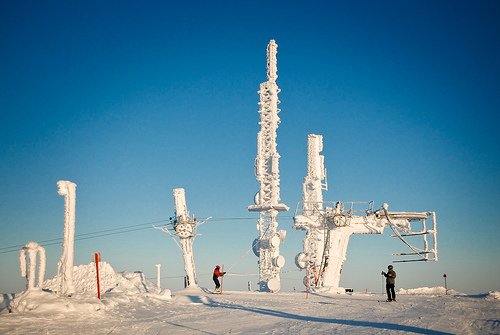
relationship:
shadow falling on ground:
[0, 313, 500, 335] [2, 290, 498, 333]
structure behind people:
[165, 188, 202, 288] [212, 265, 226, 292]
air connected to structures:
[6, 4, 490, 300] [218, 38, 408, 292]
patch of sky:
[20, 20, 239, 180] [0, 5, 495, 290]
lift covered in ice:
[350, 196, 448, 272] [309, 209, 409, 234]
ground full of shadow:
[2, 290, 498, 333] [0, 313, 500, 335]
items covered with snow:
[16, 43, 447, 298] [14, 40, 446, 299]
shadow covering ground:
[0, 313, 500, 335] [0, 284, 500, 332]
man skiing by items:
[381, 265, 396, 302] [234, 36, 449, 296]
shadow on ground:
[197, 295, 447, 333] [19, 286, 497, 333]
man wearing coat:
[381, 265, 396, 302] [380, 264, 397, 290]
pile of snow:
[42, 255, 133, 306] [12, 289, 499, 331]